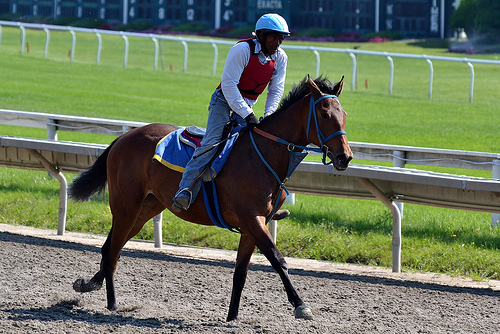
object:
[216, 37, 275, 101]
vest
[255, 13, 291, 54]
helmet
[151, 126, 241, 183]
saddle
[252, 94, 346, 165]
bridle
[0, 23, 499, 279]
grass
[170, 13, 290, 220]
jockey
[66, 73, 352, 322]
horse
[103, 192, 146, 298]
leg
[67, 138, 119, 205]
tail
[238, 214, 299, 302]
front right leg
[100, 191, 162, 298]
back two legs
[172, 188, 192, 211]
stirrup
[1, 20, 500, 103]
guard rail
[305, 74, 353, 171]
head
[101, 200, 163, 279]
legs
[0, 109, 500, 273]
fence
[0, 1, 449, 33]
wall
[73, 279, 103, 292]
hoof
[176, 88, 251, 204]
jeans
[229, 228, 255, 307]
front legs